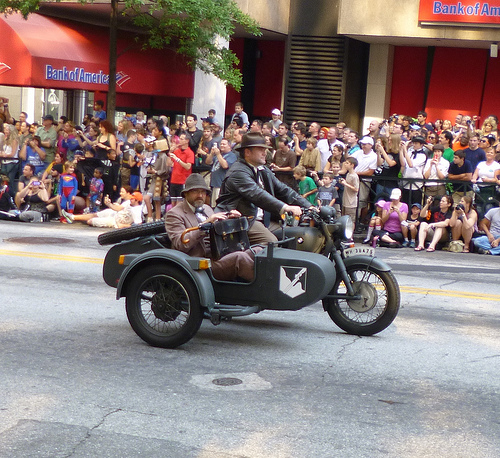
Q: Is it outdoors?
A: Yes, it is outdoors.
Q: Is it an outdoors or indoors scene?
A: It is outdoors.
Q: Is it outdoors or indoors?
A: It is outdoors.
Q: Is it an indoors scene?
A: No, it is outdoors.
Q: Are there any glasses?
A: No, there are no glasses.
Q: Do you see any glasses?
A: No, there are no glasses.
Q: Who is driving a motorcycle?
A: The man is driving a motorcycle.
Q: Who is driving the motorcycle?
A: The man is driving a motorcycle.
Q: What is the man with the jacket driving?
A: The man is driving a motorcycle.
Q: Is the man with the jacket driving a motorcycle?
A: Yes, the man is driving a motorcycle.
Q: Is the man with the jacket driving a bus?
A: No, the man is driving a motorcycle.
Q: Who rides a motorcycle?
A: The man rides a motorcycle.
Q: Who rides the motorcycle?
A: The man rides a motorcycle.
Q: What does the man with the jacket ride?
A: The man rides a motorcycle.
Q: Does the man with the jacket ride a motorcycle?
A: Yes, the man rides a motorcycle.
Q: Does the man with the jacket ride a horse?
A: No, the man rides a motorcycle.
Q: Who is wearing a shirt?
A: The man is wearing a shirt.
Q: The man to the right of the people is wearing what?
A: The man is wearing a shirt.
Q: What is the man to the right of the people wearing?
A: The man is wearing a shirt.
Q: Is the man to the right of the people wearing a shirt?
A: Yes, the man is wearing a shirt.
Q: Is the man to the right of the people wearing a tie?
A: No, the man is wearing a shirt.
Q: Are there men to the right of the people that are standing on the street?
A: Yes, there is a man to the right of the people.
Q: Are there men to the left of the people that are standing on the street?
A: No, the man is to the right of the people.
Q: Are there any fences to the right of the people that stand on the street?
A: No, there is a man to the right of the people.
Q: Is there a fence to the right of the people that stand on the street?
A: No, there is a man to the right of the people.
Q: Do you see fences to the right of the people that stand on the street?
A: No, there is a man to the right of the people.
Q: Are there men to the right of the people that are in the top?
A: Yes, there is a man to the right of the people.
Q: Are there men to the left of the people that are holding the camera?
A: No, the man is to the right of the people.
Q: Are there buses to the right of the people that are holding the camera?
A: No, there is a man to the right of the people.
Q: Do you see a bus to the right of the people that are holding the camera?
A: No, there is a man to the right of the people.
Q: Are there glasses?
A: No, there are no glasses.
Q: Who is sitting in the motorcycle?
A: The man is sitting in the motorcycle.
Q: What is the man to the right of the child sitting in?
A: The man is sitting in the motorbike.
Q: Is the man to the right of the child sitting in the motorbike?
A: Yes, the man is sitting in the motorbike.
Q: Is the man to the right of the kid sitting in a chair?
A: No, the man is sitting in the motorbike.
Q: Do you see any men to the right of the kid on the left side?
A: Yes, there is a man to the right of the child.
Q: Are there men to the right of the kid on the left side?
A: Yes, there is a man to the right of the child.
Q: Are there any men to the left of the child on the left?
A: No, the man is to the right of the child.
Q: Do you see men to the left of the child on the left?
A: No, the man is to the right of the child.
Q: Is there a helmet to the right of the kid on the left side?
A: No, there is a man to the right of the child.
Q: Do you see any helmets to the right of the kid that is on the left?
A: No, there is a man to the right of the child.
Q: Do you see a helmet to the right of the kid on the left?
A: No, there is a man to the right of the child.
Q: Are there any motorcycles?
A: Yes, there is a motorcycle.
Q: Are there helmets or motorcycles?
A: Yes, there is a motorcycle.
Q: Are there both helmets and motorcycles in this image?
A: No, there is a motorcycle but no helmets.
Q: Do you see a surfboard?
A: No, there are no surfboards.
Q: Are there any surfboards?
A: No, there are no surfboards.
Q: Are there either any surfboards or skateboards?
A: No, there are no surfboards or skateboards.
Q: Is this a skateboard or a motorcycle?
A: This is a motorcycle.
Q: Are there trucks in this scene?
A: No, there are no trucks.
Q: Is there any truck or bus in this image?
A: No, there are no trucks or buses.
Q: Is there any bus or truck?
A: No, there are no trucks or buses.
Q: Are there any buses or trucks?
A: No, there are no trucks or buses.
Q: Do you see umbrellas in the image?
A: No, there are no umbrellas.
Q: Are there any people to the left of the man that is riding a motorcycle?
A: Yes, there are people to the left of the man.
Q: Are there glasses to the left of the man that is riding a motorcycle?
A: No, there are people to the left of the man.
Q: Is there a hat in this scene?
A: Yes, there is a hat.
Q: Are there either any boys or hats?
A: Yes, there is a hat.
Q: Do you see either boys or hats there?
A: Yes, there is a hat.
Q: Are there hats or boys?
A: Yes, there is a hat.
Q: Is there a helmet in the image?
A: No, there are no helmets.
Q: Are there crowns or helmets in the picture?
A: No, there are no helmets or crowns.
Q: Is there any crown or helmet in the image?
A: No, there are no helmets or crowns.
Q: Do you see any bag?
A: Yes, there is a bag.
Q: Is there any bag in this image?
A: Yes, there is a bag.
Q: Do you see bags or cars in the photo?
A: Yes, there is a bag.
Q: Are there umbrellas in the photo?
A: No, there are no umbrellas.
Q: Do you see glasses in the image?
A: No, there are no glasses.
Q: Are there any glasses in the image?
A: No, there are no glasses.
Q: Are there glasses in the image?
A: No, there are no glasses.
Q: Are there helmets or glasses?
A: No, there are no glasses or helmets.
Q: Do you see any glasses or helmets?
A: No, there are no glasses or helmets.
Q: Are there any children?
A: Yes, there is a child.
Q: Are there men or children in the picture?
A: Yes, there is a child.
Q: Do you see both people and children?
A: Yes, there are both a child and a person.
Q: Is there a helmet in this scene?
A: No, there are no helmets.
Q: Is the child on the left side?
A: Yes, the child is on the left of the image.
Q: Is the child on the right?
A: No, the child is on the left of the image.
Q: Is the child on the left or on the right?
A: The child is on the left of the image.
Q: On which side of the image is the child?
A: The child is on the left of the image.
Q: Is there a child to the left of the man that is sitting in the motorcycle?
A: Yes, there is a child to the left of the man.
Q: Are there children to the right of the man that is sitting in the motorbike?
A: No, the child is to the left of the man.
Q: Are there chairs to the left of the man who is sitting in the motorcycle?
A: No, there is a child to the left of the man.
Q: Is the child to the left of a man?
A: Yes, the child is to the left of a man.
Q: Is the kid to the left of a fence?
A: No, the kid is to the left of a man.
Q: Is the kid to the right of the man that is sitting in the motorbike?
A: No, the kid is to the left of the man.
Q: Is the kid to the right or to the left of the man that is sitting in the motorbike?
A: The kid is to the left of the man.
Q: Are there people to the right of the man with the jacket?
A: Yes, there is a person to the right of the man.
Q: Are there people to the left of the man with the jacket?
A: No, the person is to the right of the man.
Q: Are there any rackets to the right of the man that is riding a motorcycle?
A: No, there is a person to the right of the man.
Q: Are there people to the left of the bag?
A: No, the person is to the right of the bag.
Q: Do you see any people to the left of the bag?
A: No, the person is to the right of the bag.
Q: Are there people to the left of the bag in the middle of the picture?
A: No, the person is to the right of the bag.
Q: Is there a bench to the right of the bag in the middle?
A: No, there is a person to the right of the bag.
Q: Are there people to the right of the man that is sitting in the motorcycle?
A: Yes, there is a person to the right of the man.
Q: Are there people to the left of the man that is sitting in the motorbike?
A: No, the person is to the right of the man.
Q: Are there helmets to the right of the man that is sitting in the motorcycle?
A: No, there is a person to the right of the man.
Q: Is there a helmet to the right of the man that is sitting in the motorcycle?
A: No, there is a person to the right of the man.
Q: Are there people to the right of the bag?
A: Yes, there are people to the right of the bag.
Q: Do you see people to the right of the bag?
A: Yes, there are people to the right of the bag.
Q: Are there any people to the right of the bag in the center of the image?
A: Yes, there are people to the right of the bag.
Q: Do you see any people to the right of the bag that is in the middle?
A: Yes, there are people to the right of the bag.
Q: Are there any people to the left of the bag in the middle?
A: No, the people are to the right of the bag.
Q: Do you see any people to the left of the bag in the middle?
A: No, the people are to the right of the bag.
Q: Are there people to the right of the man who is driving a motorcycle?
A: Yes, there are people to the right of the man.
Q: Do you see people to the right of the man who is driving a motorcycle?
A: Yes, there are people to the right of the man.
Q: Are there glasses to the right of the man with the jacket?
A: No, there are people to the right of the man.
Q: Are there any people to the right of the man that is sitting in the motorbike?
A: Yes, there are people to the right of the man.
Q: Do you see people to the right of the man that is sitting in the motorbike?
A: Yes, there are people to the right of the man.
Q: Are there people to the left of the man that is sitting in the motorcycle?
A: No, the people are to the right of the man.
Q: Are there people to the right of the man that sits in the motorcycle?
A: Yes, there are people to the right of the man.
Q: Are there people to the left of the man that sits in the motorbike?
A: No, the people are to the right of the man.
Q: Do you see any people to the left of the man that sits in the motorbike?
A: No, the people are to the right of the man.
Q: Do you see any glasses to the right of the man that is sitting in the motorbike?
A: No, there are people to the right of the man.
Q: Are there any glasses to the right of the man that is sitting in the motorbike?
A: No, there are people to the right of the man.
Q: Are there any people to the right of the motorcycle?
A: Yes, there are people to the right of the motorcycle.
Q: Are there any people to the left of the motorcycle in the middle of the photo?
A: No, the people are to the right of the motorcycle.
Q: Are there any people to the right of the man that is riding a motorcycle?
A: Yes, there are people to the right of the man.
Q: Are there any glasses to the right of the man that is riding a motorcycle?
A: No, there are people to the right of the man.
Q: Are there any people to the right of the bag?
A: Yes, there are people to the right of the bag.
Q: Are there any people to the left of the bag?
A: No, the people are to the right of the bag.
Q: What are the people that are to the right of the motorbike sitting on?
A: The people are sitting on the ground.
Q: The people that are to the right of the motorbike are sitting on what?
A: The people are sitting on the ground.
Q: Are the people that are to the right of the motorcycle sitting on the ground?
A: Yes, the people are sitting on the ground.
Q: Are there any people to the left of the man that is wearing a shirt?
A: Yes, there are people to the left of the man.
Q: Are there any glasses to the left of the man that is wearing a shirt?
A: No, there are people to the left of the man.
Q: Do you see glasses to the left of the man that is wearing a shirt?
A: No, there are people to the left of the man.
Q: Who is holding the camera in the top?
A: The people are holding the camera.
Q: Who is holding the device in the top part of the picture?
A: The people are holding the camera.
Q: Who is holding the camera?
A: The people are holding the camera.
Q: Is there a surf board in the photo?
A: No, there are no surfboards.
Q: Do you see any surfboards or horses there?
A: No, there are no surfboards or horses.